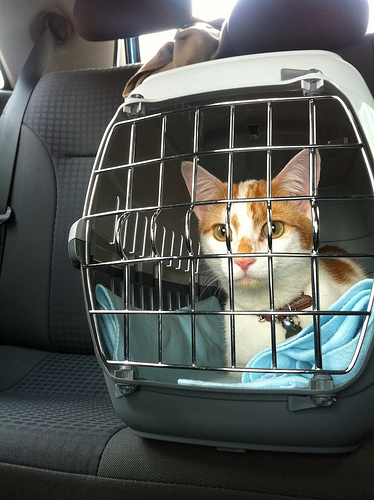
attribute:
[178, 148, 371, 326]
cat — orange, white